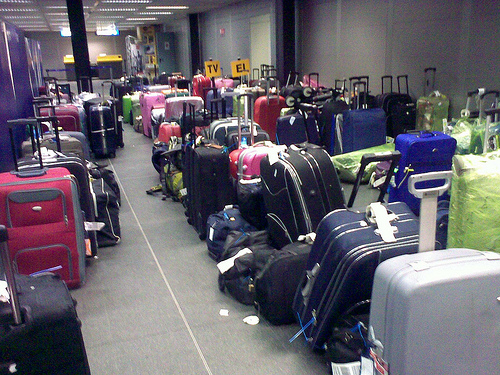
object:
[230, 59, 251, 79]
sign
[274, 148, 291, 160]
handle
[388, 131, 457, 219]
blue suitcase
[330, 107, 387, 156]
blue suitcase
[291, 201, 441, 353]
blue suitcase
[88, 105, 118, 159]
blue suitcase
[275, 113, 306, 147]
blue suitcase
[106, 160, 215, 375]
line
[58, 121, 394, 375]
floor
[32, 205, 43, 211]
button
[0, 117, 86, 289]
luggage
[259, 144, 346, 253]
suitcase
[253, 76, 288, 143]
suitcase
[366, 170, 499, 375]
suitcase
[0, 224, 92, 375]
suitcase